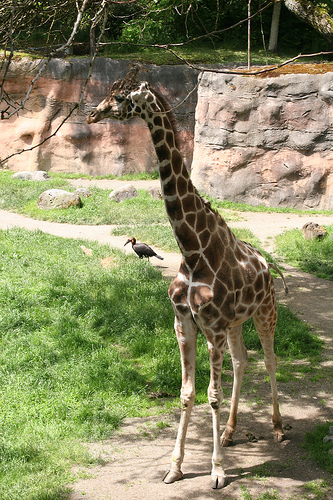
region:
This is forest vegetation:
[5, 2, 316, 70]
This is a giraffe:
[81, 52, 302, 499]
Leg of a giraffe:
[253, 301, 302, 459]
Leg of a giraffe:
[218, 315, 250, 465]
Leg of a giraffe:
[203, 306, 234, 499]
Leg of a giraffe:
[162, 283, 195, 491]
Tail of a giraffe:
[260, 249, 317, 307]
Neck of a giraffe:
[143, 113, 211, 263]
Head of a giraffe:
[72, 58, 172, 134]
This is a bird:
[115, 230, 171, 267]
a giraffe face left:
[82, 71, 297, 492]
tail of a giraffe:
[264, 251, 294, 303]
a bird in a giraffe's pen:
[117, 227, 165, 273]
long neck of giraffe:
[152, 87, 232, 242]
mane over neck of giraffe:
[153, 87, 242, 248]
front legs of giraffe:
[158, 333, 231, 492]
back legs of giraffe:
[223, 332, 291, 449]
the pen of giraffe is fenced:
[4, 38, 331, 498]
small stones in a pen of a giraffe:
[12, 158, 157, 213]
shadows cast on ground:
[193, 365, 331, 499]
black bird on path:
[122, 236, 160, 257]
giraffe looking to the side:
[81, 64, 295, 487]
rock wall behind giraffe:
[1, 52, 328, 210]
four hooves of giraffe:
[151, 437, 294, 486]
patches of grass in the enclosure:
[1, 169, 331, 498]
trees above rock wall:
[7, 1, 315, 54]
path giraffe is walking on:
[5, 205, 327, 470]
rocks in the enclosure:
[23, 180, 325, 238]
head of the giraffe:
[72, 67, 166, 125]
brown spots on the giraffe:
[137, 103, 287, 385]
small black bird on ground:
[122, 227, 162, 270]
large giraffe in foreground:
[65, 72, 302, 480]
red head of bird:
[123, 237, 139, 246]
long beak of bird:
[117, 239, 131, 250]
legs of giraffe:
[148, 320, 300, 496]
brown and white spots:
[166, 198, 201, 240]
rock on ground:
[299, 219, 326, 244]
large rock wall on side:
[196, 72, 324, 213]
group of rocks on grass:
[7, 167, 140, 224]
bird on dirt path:
[115, 231, 157, 282]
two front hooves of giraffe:
[108, 458, 241, 496]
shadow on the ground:
[89, 437, 177, 498]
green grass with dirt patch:
[0, 421, 176, 494]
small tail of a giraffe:
[249, 244, 314, 308]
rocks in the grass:
[3, 158, 154, 219]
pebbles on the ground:
[222, 408, 310, 456]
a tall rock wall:
[197, 59, 322, 207]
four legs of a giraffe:
[90, 306, 307, 498]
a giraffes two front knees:
[119, 385, 232, 424]